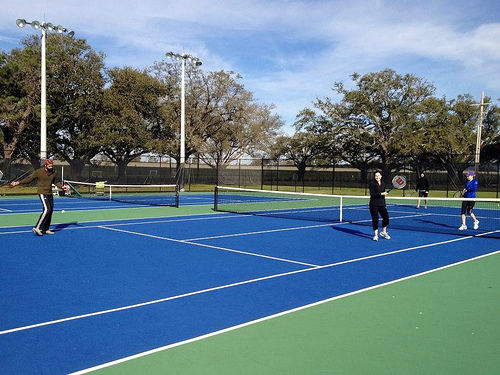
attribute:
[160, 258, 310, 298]
line — white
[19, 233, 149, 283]
area — blue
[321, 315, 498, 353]
area — green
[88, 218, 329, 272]
line — white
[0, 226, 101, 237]
line — white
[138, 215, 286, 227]
line — white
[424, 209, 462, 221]
line — white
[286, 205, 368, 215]
line — white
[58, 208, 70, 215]
tennis ball — green